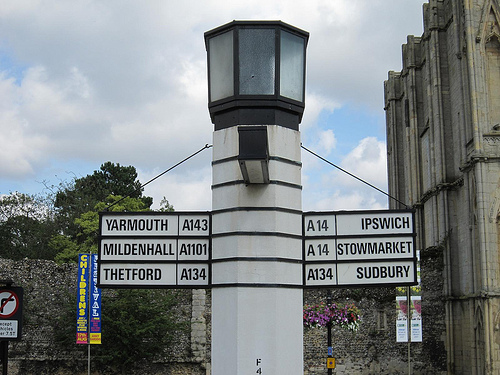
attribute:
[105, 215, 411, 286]
letters — black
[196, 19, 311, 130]
light — small, big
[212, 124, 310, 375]
post — concrete, black, white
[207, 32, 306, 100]
panes — glass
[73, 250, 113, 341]
banner — blue, tall, yellow, red, vertical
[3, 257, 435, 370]
wall — stone, tall, brick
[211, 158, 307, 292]
stripes — black, thin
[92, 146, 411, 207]
cable — black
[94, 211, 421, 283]
sign — white, small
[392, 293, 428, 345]
banner — white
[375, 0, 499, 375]
building — stone, large, tall, brick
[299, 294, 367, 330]
flowers — purple, white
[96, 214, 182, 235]
yarmouth — black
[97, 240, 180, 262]
mildenhall — black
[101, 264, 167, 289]
thetford — black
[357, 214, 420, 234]
ipswich — black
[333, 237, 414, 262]
stowmarket — black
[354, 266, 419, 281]
sudbury — black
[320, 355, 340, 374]
sign — yellow